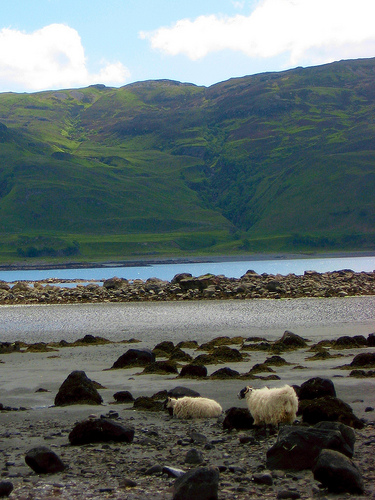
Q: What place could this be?
A: It is a beach.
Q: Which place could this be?
A: It is a beach.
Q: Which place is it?
A: It is a beach.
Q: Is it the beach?
A: Yes, it is the beach.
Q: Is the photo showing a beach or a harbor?
A: It is showing a beach.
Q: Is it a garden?
A: No, it is a beach.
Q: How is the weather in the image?
A: It is cloudy.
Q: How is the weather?
A: It is cloudy.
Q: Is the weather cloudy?
A: Yes, it is cloudy.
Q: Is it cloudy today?
A: Yes, it is cloudy.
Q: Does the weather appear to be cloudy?
A: Yes, it is cloudy.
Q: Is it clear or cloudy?
A: It is cloudy.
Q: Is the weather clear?
A: No, it is cloudy.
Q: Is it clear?
A: No, it is cloudy.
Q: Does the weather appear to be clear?
A: No, it is cloudy.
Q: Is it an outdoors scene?
A: Yes, it is outdoors.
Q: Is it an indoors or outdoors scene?
A: It is outdoors.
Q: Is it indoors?
A: No, it is outdoors.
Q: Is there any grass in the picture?
A: Yes, there is grass.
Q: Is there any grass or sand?
A: Yes, there is grass.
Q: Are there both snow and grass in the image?
A: No, there is grass but no snow.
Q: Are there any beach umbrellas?
A: No, there are no beach umbrellas.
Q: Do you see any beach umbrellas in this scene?
A: No, there are no beach umbrellas.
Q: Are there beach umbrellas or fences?
A: No, there are no beach umbrellas or fences.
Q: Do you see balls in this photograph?
A: No, there are no balls.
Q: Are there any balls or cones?
A: No, there are no balls or cones.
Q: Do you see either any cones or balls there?
A: No, there are no balls or cones.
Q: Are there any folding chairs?
A: No, there are no folding chairs.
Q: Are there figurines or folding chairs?
A: No, there are no folding chairs or figurines.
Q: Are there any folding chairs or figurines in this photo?
A: No, there are no folding chairs or figurines.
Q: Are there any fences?
A: No, there are no fences.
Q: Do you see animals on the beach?
A: Yes, there is an animal on the beach.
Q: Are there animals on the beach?
A: Yes, there is an animal on the beach.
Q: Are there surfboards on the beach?
A: No, there is an animal on the beach.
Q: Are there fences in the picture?
A: No, there are no fences.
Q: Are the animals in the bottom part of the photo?
A: Yes, the animals are in the bottom of the image.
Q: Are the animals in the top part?
A: No, the animals are in the bottom of the image.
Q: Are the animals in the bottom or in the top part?
A: The animals are in the bottom of the image.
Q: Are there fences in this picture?
A: No, there are no fences.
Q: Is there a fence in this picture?
A: No, there are no fences.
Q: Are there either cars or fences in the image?
A: No, there are no fences or cars.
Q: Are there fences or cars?
A: No, there are no fences or cars.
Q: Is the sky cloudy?
A: Yes, the sky is cloudy.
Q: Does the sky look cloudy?
A: Yes, the sky is cloudy.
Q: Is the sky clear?
A: No, the sky is cloudy.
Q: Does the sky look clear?
A: No, the sky is cloudy.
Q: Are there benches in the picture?
A: No, there are no benches.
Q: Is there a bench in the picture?
A: No, there are no benches.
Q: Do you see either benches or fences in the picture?
A: No, there are no benches or fences.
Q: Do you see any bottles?
A: Yes, there is a bottle.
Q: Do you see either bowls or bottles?
A: Yes, there is a bottle.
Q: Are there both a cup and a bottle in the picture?
A: No, there is a bottle but no cups.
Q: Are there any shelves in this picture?
A: No, there are no shelves.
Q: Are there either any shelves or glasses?
A: No, there are no shelves or glasses.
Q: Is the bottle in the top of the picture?
A: No, the bottle is in the bottom of the image.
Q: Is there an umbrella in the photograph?
A: No, there are no umbrellas.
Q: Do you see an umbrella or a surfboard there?
A: No, there are no umbrellas or surfboards.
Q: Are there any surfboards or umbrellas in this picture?
A: No, there are no umbrellas or surfboards.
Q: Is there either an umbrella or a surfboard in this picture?
A: No, there are no umbrellas or surfboards.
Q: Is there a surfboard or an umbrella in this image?
A: No, there are no umbrellas or surfboards.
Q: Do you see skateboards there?
A: No, there are no skateboards.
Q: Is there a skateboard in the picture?
A: No, there are no skateboards.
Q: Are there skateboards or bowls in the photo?
A: No, there are no skateboards or bowls.